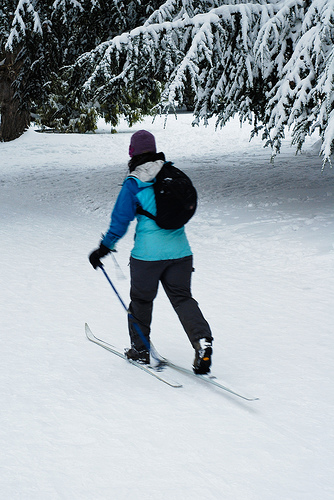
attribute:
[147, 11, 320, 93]
snow — packed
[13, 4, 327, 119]
tree — pine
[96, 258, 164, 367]
pole — blue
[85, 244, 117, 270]
glove — black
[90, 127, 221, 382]
skier — standing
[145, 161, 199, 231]
backpack — black, slung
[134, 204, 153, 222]
strap — black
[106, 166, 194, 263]
coat — blue, two tone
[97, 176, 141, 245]
sleeve — long, blue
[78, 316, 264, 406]
skis — white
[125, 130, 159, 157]
cap — knitted, purple, gray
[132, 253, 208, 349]
pants — black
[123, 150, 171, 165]
collar — black